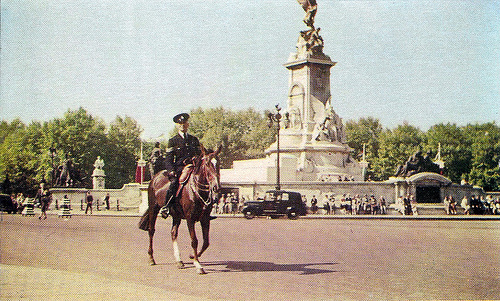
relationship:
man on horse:
[161, 112, 219, 222] [144, 149, 225, 253]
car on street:
[242, 182, 305, 222] [4, 214, 498, 298]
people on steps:
[311, 193, 499, 218] [308, 208, 498, 216]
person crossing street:
[37, 181, 52, 223] [4, 214, 498, 298]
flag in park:
[131, 157, 145, 183] [2, 117, 499, 171]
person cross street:
[37, 181, 52, 223] [4, 214, 498, 298]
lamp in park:
[265, 99, 285, 203] [2, 117, 499, 171]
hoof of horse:
[194, 262, 205, 278] [144, 149, 225, 253]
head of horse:
[202, 154, 225, 204] [144, 149, 225, 253]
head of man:
[174, 111, 194, 136] [162, 105, 200, 180]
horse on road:
[144, 149, 225, 253] [4, 214, 498, 298]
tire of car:
[247, 205, 255, 219] [242, 182, 305, 222]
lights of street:
[266, 96, 285, 128] [4, 214, 498, 298]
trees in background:
[3, 123, 499, 192] [10, 15, 491, 212]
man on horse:
[162, 105, 200, 180] [144, 149, 225, 253]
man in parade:
[162, 105, 200, 180] [4, 214, 498, 298]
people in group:
[311, 193, 499, 218] [330, 187, 459, 218]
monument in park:
[284, 0, 339, 150] [2, 117, 499, 171]